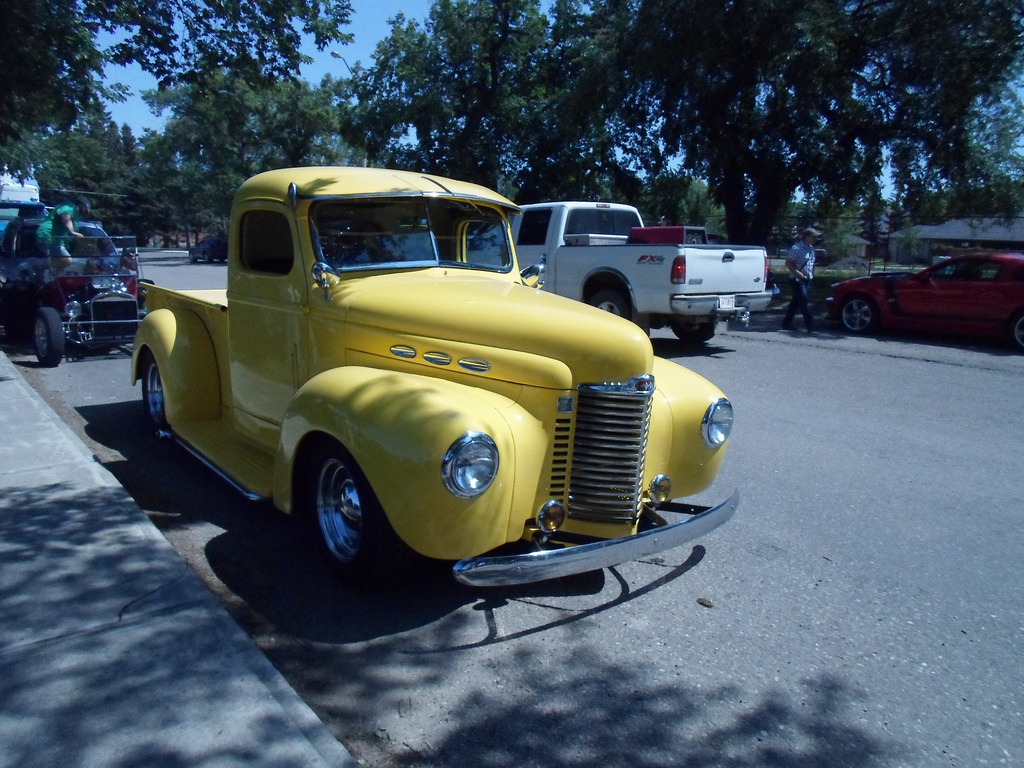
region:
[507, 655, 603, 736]
Shadow of the trees on the ground.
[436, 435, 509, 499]
Headlight in the front of the truck.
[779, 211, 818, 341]
Man walking across the road.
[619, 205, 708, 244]
Red dog cage on the back of the truck.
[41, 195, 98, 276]
Person standing on the back of the truck.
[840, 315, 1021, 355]
Bottom of a red Mustang.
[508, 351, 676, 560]
Silver grill in the front of the truck.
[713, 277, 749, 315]
White tag on the back of the truck.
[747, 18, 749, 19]
Trees above the cars.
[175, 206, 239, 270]
Car sitting on the side of the road.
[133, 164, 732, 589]
Classic yellow truck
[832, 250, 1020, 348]
Mustang is red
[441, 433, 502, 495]
Headlight on truck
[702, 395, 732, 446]
Headlight on truck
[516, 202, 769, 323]
White truck is newer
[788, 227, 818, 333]
Man in blue shirt walking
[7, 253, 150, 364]
Maroon classic car on the way to the show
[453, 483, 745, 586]
Front bumper of truck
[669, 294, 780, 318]
Back bumper of truck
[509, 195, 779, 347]
white truck in street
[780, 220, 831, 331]
man wearing a baseball cap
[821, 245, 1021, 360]
red car near curb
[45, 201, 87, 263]
person wearing green hat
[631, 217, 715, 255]
red object in back of white truck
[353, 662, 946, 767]
shadow in front of yellow truck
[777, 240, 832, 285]
blue shirt worn by man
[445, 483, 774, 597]
yellow truck has front bumper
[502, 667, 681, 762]
a shadow on the ground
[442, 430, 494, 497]
headlight on the car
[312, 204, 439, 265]
the windshield on the car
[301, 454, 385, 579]
front tire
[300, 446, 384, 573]
the tire is black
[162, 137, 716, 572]
the truck is yellow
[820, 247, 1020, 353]
the side of a red car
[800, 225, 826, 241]
a man's baseball cap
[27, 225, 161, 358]
a small old car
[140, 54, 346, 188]
a large green tree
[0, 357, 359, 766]
a long sidewalk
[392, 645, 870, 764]
a shadow of a tree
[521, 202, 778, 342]
bed of a white pick up truck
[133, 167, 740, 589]
front and side of antique truck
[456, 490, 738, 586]
shiny metal vehicle bumper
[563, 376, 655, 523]
long grill of antique vehicle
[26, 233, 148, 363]
front end of antique convertible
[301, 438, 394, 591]
tire with shiny hubcap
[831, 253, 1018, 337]
side of red sports car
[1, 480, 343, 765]
reflection of tree on sidewalk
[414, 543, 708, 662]
reflection of bumper on asphalt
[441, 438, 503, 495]
A light on a vehicle.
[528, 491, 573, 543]
A light on a vehicle.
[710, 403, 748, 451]
A light on a vehicle.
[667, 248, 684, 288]
A light on a vehicle.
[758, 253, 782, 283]
A light on a vehicle.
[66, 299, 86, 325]
A light on a vehicle.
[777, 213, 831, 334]
A person wearing a ball cap.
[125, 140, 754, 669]
An antique yellow truck.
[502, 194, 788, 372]
A white pickup truck.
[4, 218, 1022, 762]
The road.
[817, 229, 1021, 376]
A red parked car.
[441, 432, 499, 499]
part of old truck